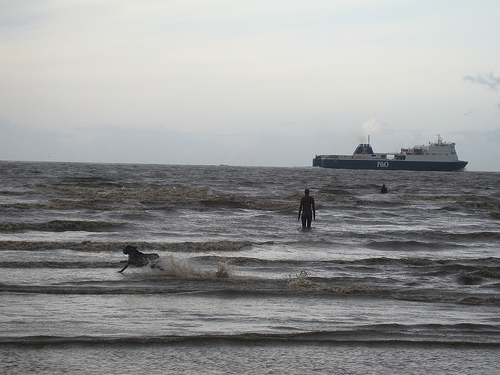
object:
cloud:
[459, 68, 499, 91]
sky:
[0, 1, 500, 173]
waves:
[157, 253, 242, 283]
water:
[0, 159, 498, 374]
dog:
[116, 243, 162, 274]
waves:
[284, 269, 373, 298]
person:
[297, 188, 316, 228]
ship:
[312, 133, 470, 172]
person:
[380, 184, 388, 194]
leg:
[117, 261, 131, 273]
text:
[383, 161, 389, 168]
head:
[304, 188, 311, 196]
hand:
[297, 215, 301, 221]